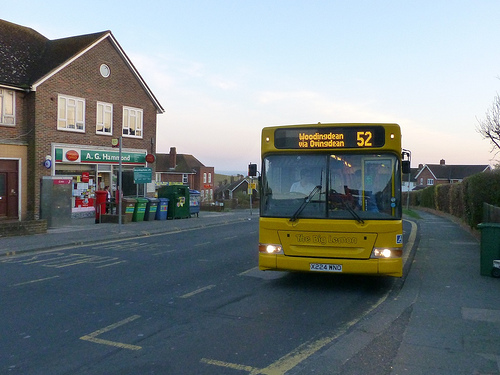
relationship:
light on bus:
[262, 241, 279, 258] [262, 119, 405, 280]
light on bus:
[375, 249, 392, 257] [262, 119, 405, 280]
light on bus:
[266, 245, 281, 254] [262, 119, 405, 280]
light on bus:
[397, 249, 404, 262] [262, 119, 405, 280]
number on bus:
[356, 131, 383, 151] [262, 119, 405, 280]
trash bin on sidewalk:
[124, 201, 132, 216] [58, 227, 128, 239]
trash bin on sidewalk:
[141, 201, 145, 220] [58, 227, 128, 239]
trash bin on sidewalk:
[151, 206, 159, 219] [58, 227, 128, 239]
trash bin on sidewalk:
[162, 200, 168, 214] [58, 227, 128, 239]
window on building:
[61, 93, 86, 129] [0, 32, 154, 171]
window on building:
[97, 101, 116, 140] [0, 32, 154, 171]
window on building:
[124, 105, 155, 140] [0, 32, 154, 171]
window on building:
[3, 91, 18, 126] [0, 32, 154, 171]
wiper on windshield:
[308, 190, 314, 198] [266, 159, 395, 220]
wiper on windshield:
[338, 196, 344, 199] [266, 159, 395, 220]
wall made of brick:
[4, 133, 25, 141] [41, 123, 46, 128]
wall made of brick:
[4, 133, 25, 141] [124, 89, 128, 92]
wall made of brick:
[4, 133, 25, 141] [55, 75, 59, 78]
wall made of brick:
[4, 133, 25, 141] [142, 144, 147, 149]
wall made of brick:
[4, 133, 25, 141] [79, 66, 85, 71]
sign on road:
[246, 163, 259, 217] [107, 255, 231, 373]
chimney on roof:
[166, 149, 178, 166] [161, 158, 166, 171]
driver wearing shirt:
[294, 172, 318, 193] [298, 185, 304, 189]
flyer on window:
[74, 191, 86, 197] [62, 170, 66, 173]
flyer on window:
[74, 191, 86, 197] [97, 101, 116, 140]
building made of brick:
[420, 164, 455, 189] [425, 172, 426, 177]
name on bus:
[300, 132, 352, 151] [262, 119, 405, 280]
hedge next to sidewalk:
[427, 193, 476, 210] [424, 211, 457, 318]